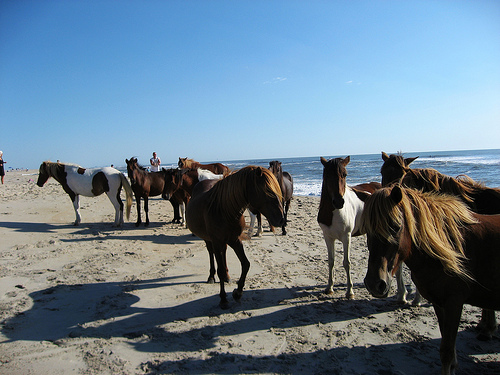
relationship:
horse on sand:
[182, 157, 296, 306] [0, 168, 499, 370]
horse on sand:
[33, 151, 136, 231] [0, 168, 499, 370]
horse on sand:
[125, 154, 192, 221] [0, 168, 499, 370]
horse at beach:
[182, 157, 296, 306] [6, 164, 499, 369]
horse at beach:
[33, 151, 136, 231] [6, 164, 499, 369]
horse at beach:
[125, 154, 192, 221] [6, 164, 499, 369]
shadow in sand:
[2, 271, 194, 339] [0, 168, 499, 370]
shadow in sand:
[83, 268, 369, 347] [0, 168, 499, 370]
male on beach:
[147, 153, 162, 175] [6, 164, 499, 369]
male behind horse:
[147, 153, 162, 175] [185, 166, 287, 312]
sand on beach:
[0, 168, 499, 370] [6, 164, 499, 369]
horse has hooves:
[182, 157, 296, 306] [206, 273, 242, 309]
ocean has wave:
[111, 135, 499, 180] [421, 149, 497, 168]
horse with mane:
[182, 157, 296, 306] [202, 160, 283, 222]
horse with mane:
[125, 154, 192, 221] [128, 159, 150, 174]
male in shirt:
[150, 152, 161, 173] [150, 156, 162, 171]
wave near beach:
[421, 149, 497, 168] [6, 164, 499, 369]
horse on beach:
[185, 166, 287, 312] [6, 164, 499, 369]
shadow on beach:
[2, 271, 194, 339] [6, 164, 499, 369]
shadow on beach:
[83, 268, 369, 347] [6, 164, 499, 369]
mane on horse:
[358, 183, 480, 281] [347, 176, 498, 371]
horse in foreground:
[347, 176, 498, 371] [1, 162, 500, 369]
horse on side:
[311, 150, 401, 301] [297, 6, 500, 374]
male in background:
[150, 152, 161, 173] [20, 0, 496, 173]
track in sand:
[71, 240, 202, 348] [0, 168, 499, 370]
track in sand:
[297, 194, 326, 308] [0, 168, 499, 370]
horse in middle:
[182, 157, 296, 306] [174, 0, 335, 372]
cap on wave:
[414, 149, 498, 164] [421, 149, 497, 168]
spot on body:
[91, 171, 110, 196] [58, 165, 126, 224]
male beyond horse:
[150, 152, 161, 173] [185, 166, 287, 312]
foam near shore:
[290, 174, 325, 199] [6, 164, 499, 369]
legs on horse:
[320, 228, 358, 304] [311, 150, 401, 301]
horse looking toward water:
[182, 157, 296, 306] [209, 155, 500, 186]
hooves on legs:
[326, 282, 359, 300] [320, 228, 358, 304]